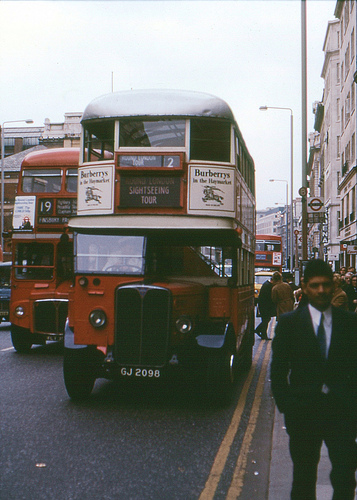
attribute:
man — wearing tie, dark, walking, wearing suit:
[268, 261, 355, 499]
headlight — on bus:
[177, 318, 193, 336]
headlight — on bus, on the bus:
[88, 311, 106, 331]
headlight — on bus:
[15, 307, 28, 317]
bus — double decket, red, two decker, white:
[66, 90, 245, 388]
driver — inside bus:
[106, 238, 138, 274]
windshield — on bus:
[72, 235, 146, 276]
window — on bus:
[122, 121, 186, 149]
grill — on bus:
[112, 287, 170, 365]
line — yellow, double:
[173, 393, 280, 498]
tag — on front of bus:
[106, 364, 164, 380]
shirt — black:
[310, 317, 326, 351]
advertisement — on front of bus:
[79, 164, 116, 215]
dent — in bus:
[202, 109, 210, 118]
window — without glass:
[189, 120, 229, 160]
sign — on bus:
[121, 178, 178, 207]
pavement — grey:
[270, 425, 288, 498]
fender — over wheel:
[197, 323, 237, 352]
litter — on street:
[245, 455, 266, 477]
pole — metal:
[298, 1, 309, 267]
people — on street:
[256, 263, 297, 340]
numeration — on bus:
[162, 157, 180, 167]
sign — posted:
[305, 197, 324, 211]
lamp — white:
[258, 105, 270, 109]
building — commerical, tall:
[318, 22, 351, 225]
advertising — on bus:
[13, 196, 34, 233]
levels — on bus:
[69, 219, 224, 232]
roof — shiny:
[91, 96, 228, 121]